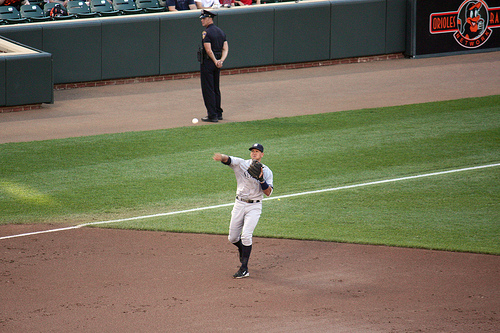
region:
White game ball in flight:
[186, 113, 204, 128]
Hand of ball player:
[208, 151, 226, 166]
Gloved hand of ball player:
[245, 160, 263, 176]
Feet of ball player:
[225, 263, 258, 285]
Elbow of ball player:
[263, 185, 277, 195]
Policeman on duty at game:
[193, 8, 233, 123]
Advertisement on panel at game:
[425, 2, 497, 57]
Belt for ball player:
[231, 194, 268, 205]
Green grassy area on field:
[305, 127, 380, 163]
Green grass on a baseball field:
[394, 198, 471, 229]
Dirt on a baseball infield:
[299, 269, 371, 301]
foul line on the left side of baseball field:
[361, 158, 445, 198]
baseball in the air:
[184, 104, 210, 133]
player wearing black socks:
[219, 231, 264, 283]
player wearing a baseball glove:
[239, 156, 271, 182]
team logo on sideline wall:
[416, 0, 498, 50]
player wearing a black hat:
[237, 136, 271, 166]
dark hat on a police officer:
[190, 4, 224, 31]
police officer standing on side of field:
[190, 10, 236, 127]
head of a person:
[243, 137, 268, 168]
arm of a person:
[215, 148, 245, 162]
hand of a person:
[205, 147, 227, 164]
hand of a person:
[240, 159, 273, 186]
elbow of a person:
[260, 185, 276, 195]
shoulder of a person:
[256, 160, 273, 172]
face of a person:
[248, 151, 260, 158]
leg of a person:
[213, 200, 238, 262]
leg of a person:
[234, 216, 267, 273]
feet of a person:
[236, 270, 256, 282]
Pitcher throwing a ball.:
[209, 139, 277, 286]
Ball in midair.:
[189, 114, 201, 127]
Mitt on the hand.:
[245, 156, 266, 186]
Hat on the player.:
[245, 136, 265, 162]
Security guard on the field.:
[192, 7, 232, 122]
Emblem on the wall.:
[423, 1, 496, 51]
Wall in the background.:
[0, 0, 496, 111]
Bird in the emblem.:
[451, 1, 486, 37]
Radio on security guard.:
[190, 40, 206, 65]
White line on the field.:
[0, 156, 498, 256]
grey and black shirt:
[224, 141, 264, 212]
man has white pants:
[220, 194, 255, 246]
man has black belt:
[237, 192, 258, 203]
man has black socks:
[227, 227, 257, 287]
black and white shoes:
[228, 259, 249, 284]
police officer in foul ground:
[191, 24, 242, 131]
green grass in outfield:
[145, 128, 239, 216]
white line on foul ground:
[28, 147, 305, 234]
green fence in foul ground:
[48, 28, 162, 75]